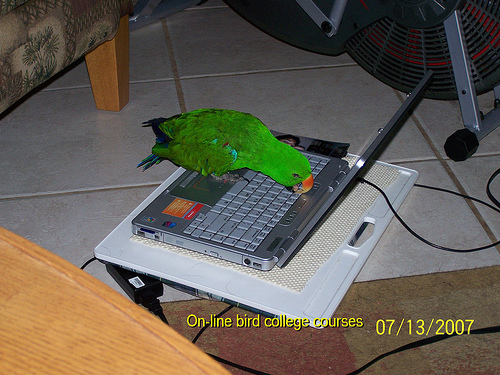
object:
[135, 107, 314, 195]
bird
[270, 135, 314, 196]
head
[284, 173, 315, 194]
beak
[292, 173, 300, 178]
eye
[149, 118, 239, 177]
wing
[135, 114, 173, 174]
tail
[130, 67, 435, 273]
laptop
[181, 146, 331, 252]
keyboard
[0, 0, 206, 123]
chair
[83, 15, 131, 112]
leg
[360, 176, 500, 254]
computer cord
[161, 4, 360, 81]
tile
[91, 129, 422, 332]
tray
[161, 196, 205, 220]
label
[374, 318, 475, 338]
date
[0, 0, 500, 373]
picture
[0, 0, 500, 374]
floor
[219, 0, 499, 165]
exercise bike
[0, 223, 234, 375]
table